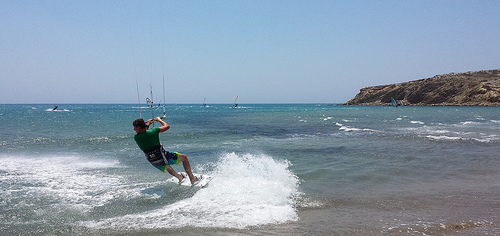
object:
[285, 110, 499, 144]
waves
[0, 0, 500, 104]
sky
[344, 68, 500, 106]
point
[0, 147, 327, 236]
wave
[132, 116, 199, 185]
man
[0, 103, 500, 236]
water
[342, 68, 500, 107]
rock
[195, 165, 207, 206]
white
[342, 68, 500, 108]
grass hill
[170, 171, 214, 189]
board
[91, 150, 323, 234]
wave top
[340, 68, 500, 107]
cliff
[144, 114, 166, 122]
bar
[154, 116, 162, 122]
hand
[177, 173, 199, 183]
feet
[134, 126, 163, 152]
shirt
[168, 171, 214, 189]
platform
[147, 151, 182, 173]
shorts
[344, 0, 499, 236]
corner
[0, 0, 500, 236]
background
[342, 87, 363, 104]
edge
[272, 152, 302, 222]
edge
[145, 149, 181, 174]
swim trunks